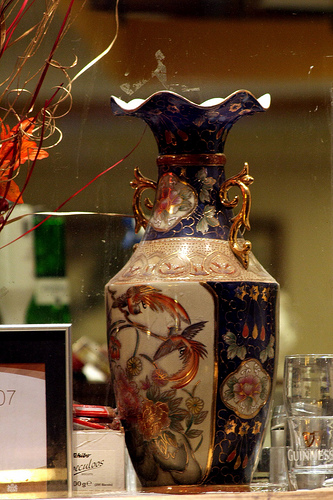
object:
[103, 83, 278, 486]
vase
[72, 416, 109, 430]
wrapper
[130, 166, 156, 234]
accent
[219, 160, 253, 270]
accent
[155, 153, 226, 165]
accent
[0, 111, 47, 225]
flower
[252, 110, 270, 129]
ground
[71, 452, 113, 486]
writing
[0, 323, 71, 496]
picture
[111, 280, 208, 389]
birds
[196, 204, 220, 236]
leaves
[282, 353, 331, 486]
bottle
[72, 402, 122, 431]
candybars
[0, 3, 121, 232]
material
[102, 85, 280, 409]
puppy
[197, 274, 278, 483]
panel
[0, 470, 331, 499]
table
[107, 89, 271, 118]
mouth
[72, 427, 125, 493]
box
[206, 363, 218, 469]
stripe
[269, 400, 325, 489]
glass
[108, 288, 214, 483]
flower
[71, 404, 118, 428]
matches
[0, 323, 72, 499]
frame